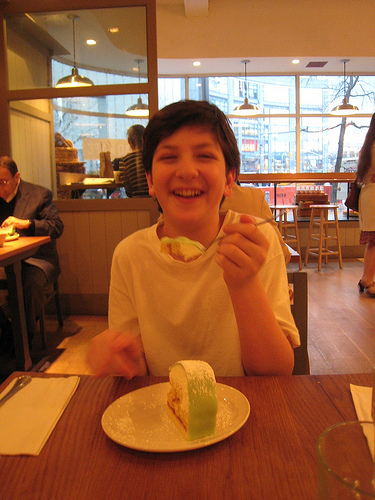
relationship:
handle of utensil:
[7, 365, 32, 392] [1, 373, 32, 407]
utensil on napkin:
[1, 373, 32, 407] [351, 379, 373, 462]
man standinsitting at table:
[1, 154, 64, 355] [282, 456, 353, 496]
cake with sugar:
[165, 356, 219, 441] [95, 381, 180, 455]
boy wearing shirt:
[91, 99, 299, 379] [101, 212, 302, 380]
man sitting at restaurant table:
[1, 154, 64, 355] [2, 231, 57, 364]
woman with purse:
[349, 111, 372, 296] [342, 178, 365, 216]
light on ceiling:
[85, 38, 96, 47] [18, 4, 350, 85]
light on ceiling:
[190, 60, 201, 66] [18, 4, 350, 85]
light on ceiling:
[291, 59, 301, 65] [18, 4, 350, 85]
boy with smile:
[91, 99, 299, 379] [162, 180, 210, 204]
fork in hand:
[159, 209, 291, 257] [213, 214, 269, 282]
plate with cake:
[98, 380, 250, 453] [165, 356, 219, 441]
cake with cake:
[165, 356, 219, 441] [165, 356, 219, 441]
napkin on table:
[0, 373, 85, 459] [28, 364, 334, 477]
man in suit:
[1, 154, 64, 355] [1, 179, 64, 341]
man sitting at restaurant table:
[1, 154, 64, 355] [0, 231, 57, 372]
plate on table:
[98, 380, 250, 453] [0, 370, 375, 500]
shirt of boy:
[101, 212, 302, 380] [78, 90, 301, 380]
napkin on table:
[0, 373, 85, 459] [0, 369, 373, 497]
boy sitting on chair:
[91, 89, 288, 391] [260, 259, 324, 371]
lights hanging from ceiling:
[37, 80, 347, 119] [35, 10, 346, 85]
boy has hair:
[91, 99, 299, 379] [141, 100, 239, 174]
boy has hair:
[91, 99, 299, 379] [155, 102, 279, 153]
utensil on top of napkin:
[1, 373, 32, 407] [0, 373, 80, 454]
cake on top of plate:
[165, 356, 219, 441] [106, 376, 260, 453]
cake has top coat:
[165, 356, 219, 441] [173, 358, 215, 441]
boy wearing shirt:
[91, 99, 299, 379] [113, 208, 301, 376]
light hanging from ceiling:
[54, 15, 95, 92] [29, 1, 374, 77]